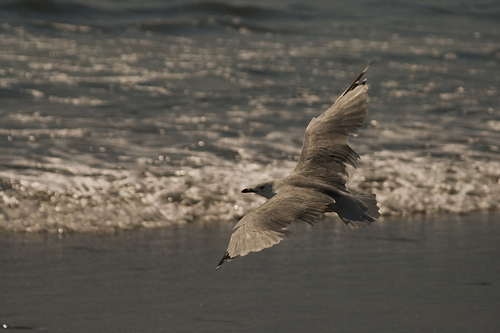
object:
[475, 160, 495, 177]
waves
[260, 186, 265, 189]
eye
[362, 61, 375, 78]
feathers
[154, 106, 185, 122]
ocean water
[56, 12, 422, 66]
ocean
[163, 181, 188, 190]
water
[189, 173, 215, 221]
water rolling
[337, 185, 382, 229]
tail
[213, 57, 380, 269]
bird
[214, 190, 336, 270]
wing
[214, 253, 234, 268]
tip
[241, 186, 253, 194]
beak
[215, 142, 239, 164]
wave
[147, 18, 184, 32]
wave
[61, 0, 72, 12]
water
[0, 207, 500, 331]
beach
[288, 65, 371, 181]
wings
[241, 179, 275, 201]
head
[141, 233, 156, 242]
sand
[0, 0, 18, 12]
water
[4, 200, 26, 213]
water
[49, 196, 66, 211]
ripples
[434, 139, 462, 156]
wave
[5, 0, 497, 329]
air